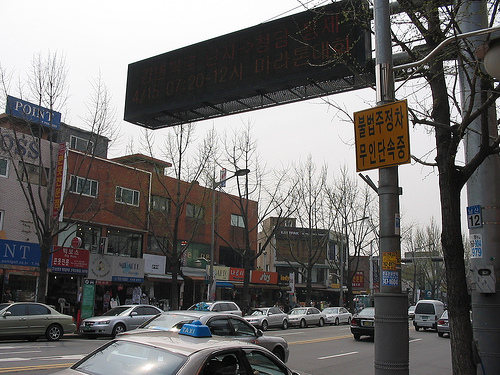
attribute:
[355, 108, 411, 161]
sign — yellow, black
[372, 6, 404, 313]
post — metal, silver, grey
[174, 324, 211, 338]
taxi cab sign — blue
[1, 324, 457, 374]
street — black, pavement, dirty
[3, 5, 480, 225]
sky — cloudy, white, blue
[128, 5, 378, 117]
street signal — black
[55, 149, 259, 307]
building — brown, red brick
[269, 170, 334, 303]
tree — brown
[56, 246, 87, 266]
sign — red, white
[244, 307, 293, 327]
car — silver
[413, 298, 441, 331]
van — large, white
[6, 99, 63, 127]
sign — blue, white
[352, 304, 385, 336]
car — black